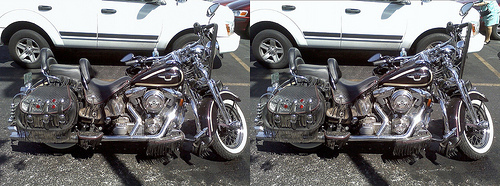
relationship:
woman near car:
[474, 0, 500, 44] [250, 0, 487, 69]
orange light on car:
[225, 23, 232, 36] [1, 1, 240, 69]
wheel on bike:
[210, 98, 249, 159] [8, 4, 248, 161]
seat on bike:
[41, 46, 131, 102] [8, 4, 248, 161]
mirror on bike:
[207, 4, 221, 16] [8, 4, 248, 161]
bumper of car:
[216, 33, 242, 54] [1, 1, 240, 69]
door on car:
[98, 0, 162, 53] [1, 1, 240, 69]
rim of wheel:
[17, 37, 41, 62] [7, 28, 50, 69]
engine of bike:
[79, 86, 186, 136] [8, 4, 248, 161]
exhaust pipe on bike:
[9, 106, 178, 143] [8, 4, 248, 161]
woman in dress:
[474, 0, 500, 44] [478, 1, 500, 27]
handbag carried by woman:
[476, 1, 490, 16] [474, 0, 500, 44]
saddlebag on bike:
[14, 85, 77, 143] [8, 4, 248, 161]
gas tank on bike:
[131, 60, 186, 88] [8, 4, 248, 161]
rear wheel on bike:
[41, 142, 80, 152] [8, 4, 248, 161]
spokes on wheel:
[218, 104, 243, 145] [210, 98, 249, 159]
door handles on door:
[99, 8, 118, 14] [98, 0, 162, 53]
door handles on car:
[99, 8, 118, 14] [1, 1, 240, 69]